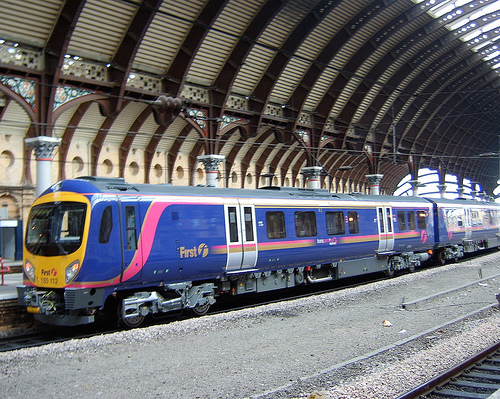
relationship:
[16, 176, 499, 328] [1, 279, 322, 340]
train on tracks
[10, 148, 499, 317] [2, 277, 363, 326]
train on tracks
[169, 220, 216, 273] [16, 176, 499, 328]
logo on train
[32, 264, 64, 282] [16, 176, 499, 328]
number on train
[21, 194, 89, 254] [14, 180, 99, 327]
windshield on front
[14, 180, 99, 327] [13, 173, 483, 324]
front of train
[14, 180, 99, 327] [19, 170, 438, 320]
front of train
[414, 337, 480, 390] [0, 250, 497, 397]
tracks on pavement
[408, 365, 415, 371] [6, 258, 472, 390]
stones on ground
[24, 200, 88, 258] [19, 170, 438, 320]
windshield on train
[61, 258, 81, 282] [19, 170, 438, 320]
light on train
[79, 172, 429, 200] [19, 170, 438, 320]
roof of train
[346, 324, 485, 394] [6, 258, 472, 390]
stones on ground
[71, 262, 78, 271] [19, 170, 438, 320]
light on train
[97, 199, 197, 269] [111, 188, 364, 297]
stripe on train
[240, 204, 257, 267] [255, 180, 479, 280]
doors on train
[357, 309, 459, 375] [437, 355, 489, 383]
gravel on tracks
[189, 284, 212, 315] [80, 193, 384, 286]
wheels on train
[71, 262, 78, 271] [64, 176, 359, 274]
light on train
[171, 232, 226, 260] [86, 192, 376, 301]
words on train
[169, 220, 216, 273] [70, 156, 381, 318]
logo on train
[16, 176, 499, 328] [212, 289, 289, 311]
train on tracks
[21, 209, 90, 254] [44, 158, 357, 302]
window on train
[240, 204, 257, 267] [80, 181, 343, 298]
doors on train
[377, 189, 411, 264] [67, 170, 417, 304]
doors on train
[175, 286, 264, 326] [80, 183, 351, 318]
wheels on train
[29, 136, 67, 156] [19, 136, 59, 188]
decoration on column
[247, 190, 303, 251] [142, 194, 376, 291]
window on train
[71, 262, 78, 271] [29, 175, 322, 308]
light on car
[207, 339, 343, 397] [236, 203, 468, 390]
pavement between tracks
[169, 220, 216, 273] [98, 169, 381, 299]
logo on train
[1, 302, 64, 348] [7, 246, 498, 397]
gravel in between tracks